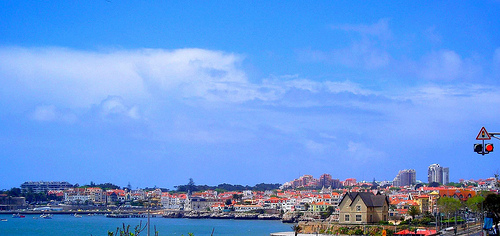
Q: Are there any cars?
A: No, there are no cars.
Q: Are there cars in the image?
A: No, there are no cars.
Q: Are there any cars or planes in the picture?
A: No, there are no cars or planes.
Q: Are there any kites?
A: No, there are no kites.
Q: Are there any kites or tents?
A: No, there are no kites or tents.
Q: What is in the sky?
A: The clouds are in the sky.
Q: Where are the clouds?
A: The clouds are in the sky.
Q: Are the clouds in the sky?
A: Yes, the clouds are in the sky.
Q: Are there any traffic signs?
A: Yes, there is a traffic sign.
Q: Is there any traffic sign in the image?
A: Yes, there is a traffic sign.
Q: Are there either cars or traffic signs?
A: Yes, there is a traffic sign.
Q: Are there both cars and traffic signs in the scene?
A: No, there is a traffic sign but no cars.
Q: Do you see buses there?
A: No, there are no buses.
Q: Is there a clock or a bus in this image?
A: No, there are no buses or clocks.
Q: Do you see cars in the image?
A: No, there are no cars.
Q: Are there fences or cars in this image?
A: No, there are no cars or fences.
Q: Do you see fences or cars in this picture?
A: No, there are no cars or fences.